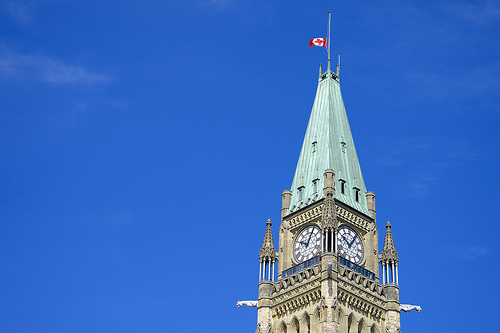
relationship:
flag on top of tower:
[293, 28, 337, 58] [269, 56, 396, 260]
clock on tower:
[292, 225, 322, 263] [227, 6, 434, 331]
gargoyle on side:
[387, 291, 431, 321] [327, 198, 421, 333]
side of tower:
[327, 198, 421, 333] [231, 14, 423, 329]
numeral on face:
[308, 220, 317, 230] [293, 224, 323, 261]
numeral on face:
[313, 230, 323, 237] [293, 224, 323, 261]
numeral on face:
[316, 232, 323, 240] [293, 224, 323, 261]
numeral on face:
[316, 240, 324, 250] [293, 224, 323, 261]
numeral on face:
[312, 249, 316, 258] [293, 224, 323, 261]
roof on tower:
[307, 66, 364, 196] [280, 58, 386, 325]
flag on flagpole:
[308, 37, 327, 48] [322, 9, 335, 74]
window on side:
[346, 310, 355, 330] [326, 193, 404, 331]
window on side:
[355, 315, 367, 331] [326, 193, 404, 331]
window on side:
[369, 320, 378, 331] [326, 193, 404, 331]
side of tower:
[326, 193, 404, 331] [233, 69, 413, 329]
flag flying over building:
[308, 37, 327, 48] [248, 52, 403, 330]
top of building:
[273, 50, 401, 274] [248, 52, 403, 330]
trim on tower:
[270, 264, 322, 315] [234, 53, 423, 332]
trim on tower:
[339, 262, 390, 319] [234, 53, 423, 332]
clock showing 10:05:
[337, 221, 367, 268] [294, 226, 320, 247]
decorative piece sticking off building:
[236, 298, 258, 308] [234, 4, 426, 331]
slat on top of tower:
[326, 7, 333, 77] [211, 39, 426, 328]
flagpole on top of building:
[309, 10, 332, 73] [234, 4, 426, 331]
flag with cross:
[308, 37, 327, 48] [314, 38, 323, 44]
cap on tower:
[289, 76, 371, 214] [250, 3, 406, 331]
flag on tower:
[308, 37, 327, 48] [234, 53, 423, 332]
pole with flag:
[327, 11, 331, 71] [301, 30, 329, 55]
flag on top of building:
[308, 37, 327, 48] [234, 4, 426, 331]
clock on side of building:
[292, 225, 322, 263] [275, 40, 401, 331]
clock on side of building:
[292, 225, 322, 263] [234, 4, 426, 331]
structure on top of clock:
[219, 79, 399, 330] [268, 204, 415, 252]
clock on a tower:
[337, 226, 364, 264] [250, 3, 406, 331]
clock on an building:
[292, 225, 322, 263] [236, 12, 422, 333]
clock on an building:
[337, 226, 364, 264] [236, 12, 422, 333]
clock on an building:
[288, 221, 372, 266] [234, 4, 426, 331]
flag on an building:
[308, 37, 327, 48] [234, 4, 426, 331]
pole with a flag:
[327, 11, 331, 71] [309, 35, 329, 57]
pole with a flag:
[312, 8, 334, 68] [308, 35, 328, 50]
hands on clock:
[284, 221, 324, 248] [290, 222, 322, 266]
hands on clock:
[285, 218, 317, 246] [286, 215, 370, 256]